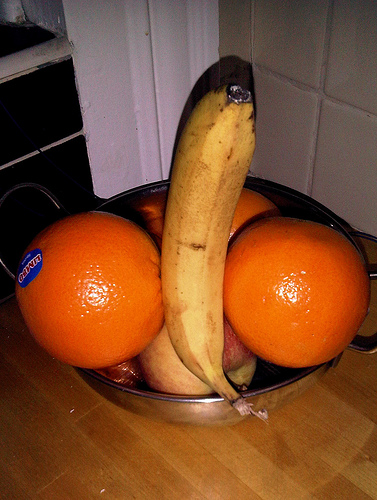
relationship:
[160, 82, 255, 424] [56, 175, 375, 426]
banana inside of fruit bowl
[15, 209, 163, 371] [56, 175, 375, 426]
orange inside fruit bowl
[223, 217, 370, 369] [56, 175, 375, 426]
orange inside fruit bowl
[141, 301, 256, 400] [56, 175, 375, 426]
apple inside fruit bowl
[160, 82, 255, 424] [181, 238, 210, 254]
banana has dark spot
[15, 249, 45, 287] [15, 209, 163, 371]
red sticker attached to orange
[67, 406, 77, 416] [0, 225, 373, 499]
spot on top of table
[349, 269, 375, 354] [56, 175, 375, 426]
handle attached to fruit bowl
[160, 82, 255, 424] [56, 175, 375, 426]
banana inside fruit bowl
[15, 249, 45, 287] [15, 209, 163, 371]
sticker attached to orange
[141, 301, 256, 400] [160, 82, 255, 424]
apple underneath banana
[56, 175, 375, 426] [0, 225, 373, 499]
fruit bowl on top of table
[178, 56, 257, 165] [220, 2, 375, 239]
shadow on wall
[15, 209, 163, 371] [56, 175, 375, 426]
orange inside of fruit bowl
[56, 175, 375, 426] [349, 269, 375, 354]
fruit bowl has handle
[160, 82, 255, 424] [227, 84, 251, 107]
banana has dark spot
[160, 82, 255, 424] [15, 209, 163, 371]
banana between orange